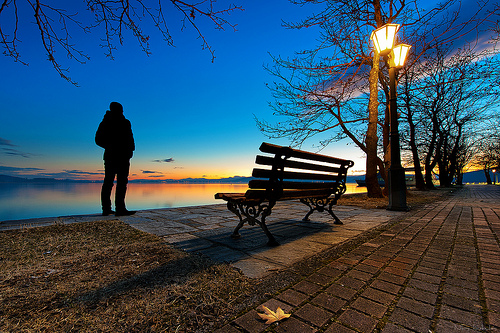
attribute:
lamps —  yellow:
[338, 17, 430, 104]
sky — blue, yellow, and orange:
[1, 2, 494, 172]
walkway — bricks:
[231, 183, 496, 329]